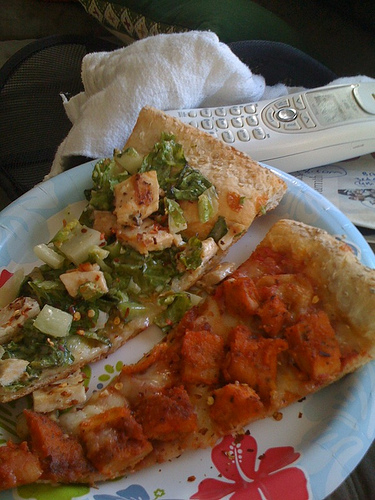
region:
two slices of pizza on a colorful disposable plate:
[1, 104, 370, 497]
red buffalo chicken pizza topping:
[204, 378, 261, 428]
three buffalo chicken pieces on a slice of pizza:
[177, 325, 287, 430]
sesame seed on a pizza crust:
[299, 228, 308, 239]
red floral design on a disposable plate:
[188, 429, 314, 498]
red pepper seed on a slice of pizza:
[87, 307, 97, 316]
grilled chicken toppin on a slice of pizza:
[112, 169, 162, 224]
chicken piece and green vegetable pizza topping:
[108, 223, 177, 310]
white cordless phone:
[159, 81, 373, 176]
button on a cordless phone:
[242, 103, 259, 113]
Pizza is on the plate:
[27, 154, 342, 439]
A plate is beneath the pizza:
[20, 155, 350, 488]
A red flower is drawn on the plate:
[210, 437, 300, 497]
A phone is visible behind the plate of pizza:
[143, 75, 368, 175]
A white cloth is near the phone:
[75, 40, 248, 142]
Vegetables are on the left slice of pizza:
[48, 225, 161, 315]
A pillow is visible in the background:
[89, 0, 294, 55]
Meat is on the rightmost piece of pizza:
[179, 282, 335, 385]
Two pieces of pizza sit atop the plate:
[23, 129, 346, 455]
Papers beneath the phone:
[294, 157, 373, 227]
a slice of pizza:
[172, 300, 241, 382]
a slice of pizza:
[119, 324, 234, 424]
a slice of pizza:
[146, 367, 209, 428]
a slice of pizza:
[135, 333, 205, 393]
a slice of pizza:
[170, 327, 270, 466]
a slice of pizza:
[206, 395, 241, 442]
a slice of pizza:
[159, 340, 191, 431]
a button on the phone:
[241, 100, 256, 113]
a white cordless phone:
[155, 77, 373, 175]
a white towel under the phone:
[37, 24, 267, 184]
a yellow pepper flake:
[85, 306, 96, 317]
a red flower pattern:
[188, 425, 310, 498]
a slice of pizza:
[0, 216, 374, 492]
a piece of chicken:
[109, 167, 163, 228]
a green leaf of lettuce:
[193, 182, 223, 225]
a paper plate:
[0, 150, 373, 498]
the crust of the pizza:
[261, 211, 374, 351]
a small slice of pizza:
[0, 219, 371, 483]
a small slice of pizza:
[2, 99, 292, 401]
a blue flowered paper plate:
[6, 151, 363, 496]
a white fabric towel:
[45, 30, 258, 162]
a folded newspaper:
[284, 155, 374, 241]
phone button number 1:
[242, 102, 254, 114]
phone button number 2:
[245, 112, 257, 125]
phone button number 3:
[251, 124, 262, 138]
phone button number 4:
[231, 104, 239, 114]